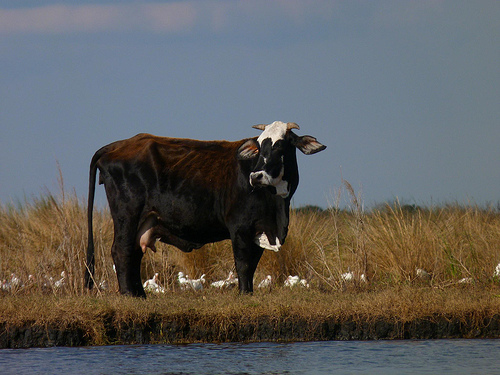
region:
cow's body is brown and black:
[33, 91, 331, 285]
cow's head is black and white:
[230, 83, 322, 213]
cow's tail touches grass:
[50, 139, 125, 304]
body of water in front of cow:
[0, 328, 491, 373]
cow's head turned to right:
[218, 93, 352, 193]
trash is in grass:
[13, 237, 473, 319]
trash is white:
[0, 254, 494, 313]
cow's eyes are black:
[250, 141, 301, 167]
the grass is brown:
[0, 183, 485, 368]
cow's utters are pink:
[119, 207, 186, 279]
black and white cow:
[71, 106, 320, 312]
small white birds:
[147, 267, 243, 299]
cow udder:
[125, 206, 169, 258]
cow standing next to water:
[73, 102, 335, 374]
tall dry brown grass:
[333, 176, 476, 288]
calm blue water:
[90, 345, 360, 372]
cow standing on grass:
[63, 103, 319, 343]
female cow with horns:
[66, 101, 331, 299]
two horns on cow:
[245, 115, 306, 135]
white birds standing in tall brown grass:
[164, 267, 231, 291]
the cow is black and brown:
[87, 109, 313, 286]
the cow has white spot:
[250, 120, 297, 189]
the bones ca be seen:
[135, 140, 191, 177]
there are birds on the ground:
[149, 264, 356, 292]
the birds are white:
[158, 264, 308, 294]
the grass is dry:
[339, 215, 481, 260]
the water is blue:
[140, 342, 406, 364]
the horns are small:
[242, 115, 309, 138]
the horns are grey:
[252, 115, 299, 133]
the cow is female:
[65, 125, 335, 287]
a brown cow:
[55, 90, 333, 310]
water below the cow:
[158, 351, 321, 367]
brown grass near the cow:
[365, 255, 443, 311]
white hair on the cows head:
[268, 124, 283, 136]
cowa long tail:
[73, 194, 102, 291]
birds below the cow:
[146, 254, 206, 302]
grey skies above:
[283, 25, 455, 110]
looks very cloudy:
[124, 52, 263, 96]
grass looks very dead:
[363, 212, 473, 236]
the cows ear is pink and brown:
[295, 122, 328, 160]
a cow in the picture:
[80, 90, 331, 295]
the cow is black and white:
[54, 120, 321, 295]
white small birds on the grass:
[0, 257, 499, 312]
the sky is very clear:
[0, 0, 499, 222]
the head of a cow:
[246, 110, 312, 200]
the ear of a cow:
[296, 133, 327, 158]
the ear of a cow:
[226, 138, 259, 163]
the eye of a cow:
[271, 134, 282, 156]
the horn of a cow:
[283, 121, 301, 133]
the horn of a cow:
[253, 123, 268, 137]